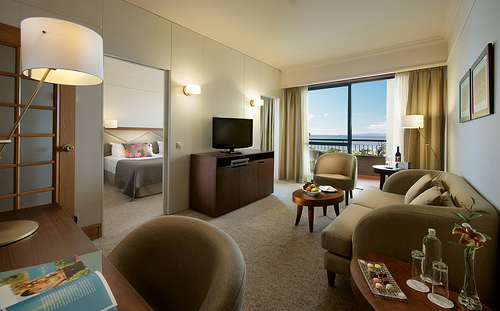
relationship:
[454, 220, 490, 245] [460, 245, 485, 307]
flower in vase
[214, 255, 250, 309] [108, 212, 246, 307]
edge of a chair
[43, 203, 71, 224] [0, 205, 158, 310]
edge of table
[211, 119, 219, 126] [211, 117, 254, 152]
edge of tv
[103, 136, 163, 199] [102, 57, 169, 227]
bed in room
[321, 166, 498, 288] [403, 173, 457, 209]
couch have pillows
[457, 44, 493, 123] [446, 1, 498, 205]
pictures on wall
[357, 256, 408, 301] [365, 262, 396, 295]
tray of assorted candies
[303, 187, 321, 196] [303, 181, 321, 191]
bowl of assorted fruits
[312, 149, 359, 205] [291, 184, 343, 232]
chair near coffee table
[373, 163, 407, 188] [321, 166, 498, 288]
side table beside couch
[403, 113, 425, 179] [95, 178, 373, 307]
lamp on floor